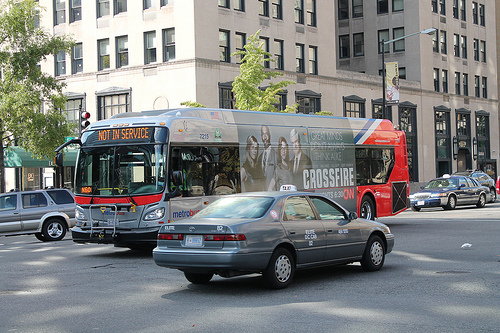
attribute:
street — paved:
[0, 195, 499, 332]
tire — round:
[39, 213, 70, 245]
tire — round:
[260, 241, 300, 295]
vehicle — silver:
[0, 183, 83, 242]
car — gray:
[148, 186, 399, 290]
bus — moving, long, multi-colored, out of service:
[68, 102, 411, 253]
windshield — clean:
[69, 127, 173, 201]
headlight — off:
[73, 205, 92, 224]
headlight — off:
[133, 199, 178, 223]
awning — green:
[1, 130, 91, 178]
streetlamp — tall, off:
[375, 24, 436, 141]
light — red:
[78, 106, 92, 135]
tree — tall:
[0, 1, 79, 231]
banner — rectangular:
[379, 54, 403, 111]